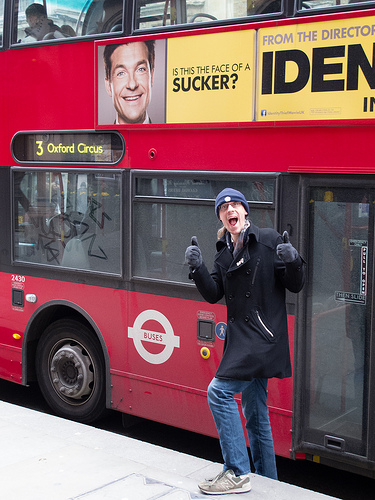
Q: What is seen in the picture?
A: Bus.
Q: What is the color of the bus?
A: Red.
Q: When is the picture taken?
A: Daytime.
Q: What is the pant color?
A: Blue.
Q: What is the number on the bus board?
A: 3.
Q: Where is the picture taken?
A: Bus stop.